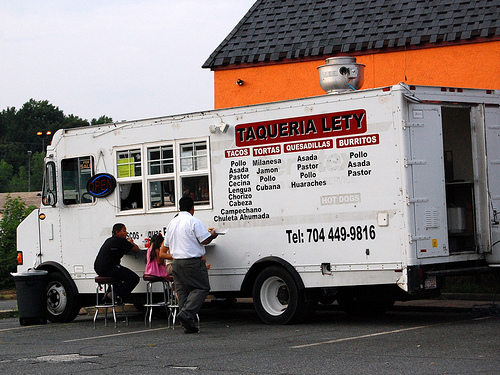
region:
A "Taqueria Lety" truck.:
[228, 109, 370, 141]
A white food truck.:
[13, 81, 493, 319]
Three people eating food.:
[94, 166, 228, 338]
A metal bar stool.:
[87, 273, 128, 328]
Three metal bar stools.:
[90, 271, 204, 331]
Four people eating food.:
[98, 194, 228, 339]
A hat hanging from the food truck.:
[85, 149, 117, 204]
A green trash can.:
[3, 262, 53, 329]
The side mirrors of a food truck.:
[35, 155, 62, 219]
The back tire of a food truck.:
[250, 246, 307, 331]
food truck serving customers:
[7, 97, 467, 348]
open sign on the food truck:
[83, 170, 113, 204]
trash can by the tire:
[12, 258, 50, 330]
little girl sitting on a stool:
[145, 235, 167, 279]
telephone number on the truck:
[283, 219, 378, 244]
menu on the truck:
[207, 120, 368, 225]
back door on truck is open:
[448, 98, 499, 255]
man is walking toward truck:
[149, 187, 221, 333]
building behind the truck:
[226, 33, 486, 97]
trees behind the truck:
[10, 99, 44, 173]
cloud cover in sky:
[0, 1, 256, 126]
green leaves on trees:
[1, 99, 116, 191]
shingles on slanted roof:
[207, 2, 497, 67]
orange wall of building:
[213, 42, 497, 108]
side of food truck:
[18, 84, 498, 324]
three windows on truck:
[114, 138, 211, 214]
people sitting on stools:
[93, 222, 195, 328]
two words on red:
[234, 108, 367, 148]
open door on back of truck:
[401, 85, 496, 264]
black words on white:
[213, 151, 370, 222]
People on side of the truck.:
[103, 189, 218, 327]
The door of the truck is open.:
[444, 100, 499, 249]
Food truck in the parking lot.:
[79, 110, 463, 284]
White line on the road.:
[290, 320, 420, 350]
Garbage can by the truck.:
[8, 259, 60, 332]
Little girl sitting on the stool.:
[136, 230, 172, 281]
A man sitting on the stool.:
[83, 223, 133, 295]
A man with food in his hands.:
[197, 213, 215, 252]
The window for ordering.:
[106, 133, 220, 208]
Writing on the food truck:
[223, 112, 375, 206]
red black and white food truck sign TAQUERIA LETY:
[233, 108, 368, 146]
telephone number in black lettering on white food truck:
[283, 223, 376, 243]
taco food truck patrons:
[91, 195, 224, 335]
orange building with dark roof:
[201, 1, 498, 109]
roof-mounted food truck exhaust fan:
[316, 54, 363, 93]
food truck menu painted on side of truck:
[211, 108, 382, 224]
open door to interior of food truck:
[441, 103, 483, 255]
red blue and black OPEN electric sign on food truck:
[88, 148, 114, 198]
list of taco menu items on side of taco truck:
[213, 145, 268, 220]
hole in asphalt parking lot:
[31, 352, 101, 362]